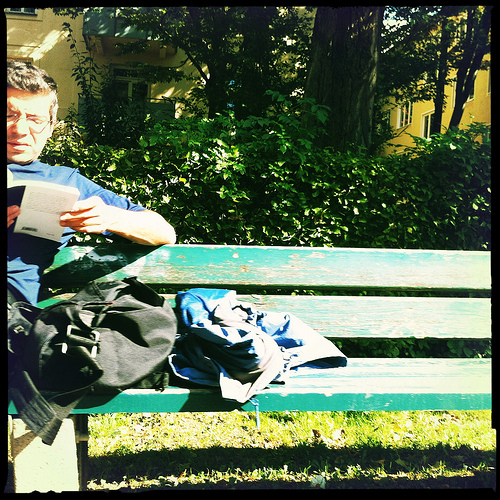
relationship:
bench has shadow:
[11, 230, 497, 494] [9, 426, 498, 496]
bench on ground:
[11, 230, 497, 494] [0, 405, 497, 498]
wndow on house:
[87, 70, 166, 128] [365, 0, 496, 158]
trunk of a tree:
[304, 1, 388, 146] [172, 2, 489, 248]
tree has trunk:
[62, 0, 490, 209] [428, 22, 451, 129]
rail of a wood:
[63, 215, 495, 350] [171, 234, 498, 341]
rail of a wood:
[37, 242, 494, 375] [379, 256, 457, 383]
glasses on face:
[2, 111, 43, 135] [8, 111, 55, 132]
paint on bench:
[191, 243, 251, 274] [11, 230, 497, 494]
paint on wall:
[443, 56, 496, 131] [386, 68, 428, 143]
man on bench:
[4, 45, 126, 275] [107, 260, 438, 403]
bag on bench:
[0, 277, 180, 394] [9, 232, 491, 412]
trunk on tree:
[304, 1, 388, 146] [308, 0, 384, 150]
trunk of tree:
[208, 52, 230, 117] [113, 0, 232, 117]